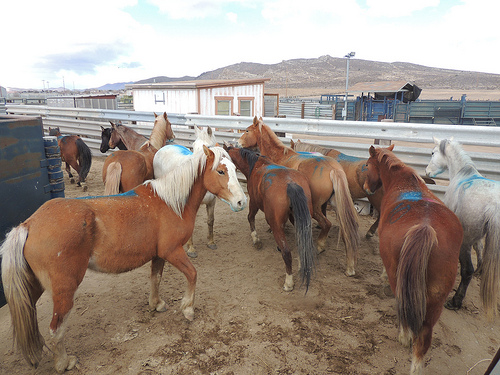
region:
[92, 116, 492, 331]
the horses are gathered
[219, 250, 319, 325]
footprints are in the dirt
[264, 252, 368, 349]
the horses are walking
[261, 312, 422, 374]
dirt is on the ground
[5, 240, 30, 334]
the horse has light hair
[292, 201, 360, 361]
the horse has dirty hair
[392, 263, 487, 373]
the horse has brown hair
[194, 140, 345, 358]
the horse has a brown and white face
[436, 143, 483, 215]
the horse is white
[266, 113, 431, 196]
the fence is by the horse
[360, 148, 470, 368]
the horse is brown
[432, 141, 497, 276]
the horse is white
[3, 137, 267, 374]
horse turned to right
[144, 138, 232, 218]
horse has white main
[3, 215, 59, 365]
horse has white tail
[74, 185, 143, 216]
blue paint on horses back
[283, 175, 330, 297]
horse has black tail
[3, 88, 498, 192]
metal fence by horses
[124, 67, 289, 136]
small building other side of fence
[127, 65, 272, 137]
small building is white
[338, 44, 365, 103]
lamp post in distance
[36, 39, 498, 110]
mountains in background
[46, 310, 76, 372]
leg of a horse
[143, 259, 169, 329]
leg of a horse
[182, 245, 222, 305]
leg of a horse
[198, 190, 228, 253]
leg of a horse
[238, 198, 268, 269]
leg of a horse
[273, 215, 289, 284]
leg of a horse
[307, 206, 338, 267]
leg of a horse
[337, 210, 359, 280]
leg of a horse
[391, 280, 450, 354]
leg of a horse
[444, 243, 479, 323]
leg of a horse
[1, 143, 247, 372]
brown horse next to brown horse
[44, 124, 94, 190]
brown horse next to brown horse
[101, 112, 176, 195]
brown horse next to brown horse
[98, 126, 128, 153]
brown horse next to brown horse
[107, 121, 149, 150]
brown horse next to brown horse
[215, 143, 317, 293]
brown horse next to brown horse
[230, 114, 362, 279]
brown horse next to brown horse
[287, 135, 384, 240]
brown horse next to brown horse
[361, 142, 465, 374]
brown horse next to brown horse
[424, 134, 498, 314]
brown horse next to white horse